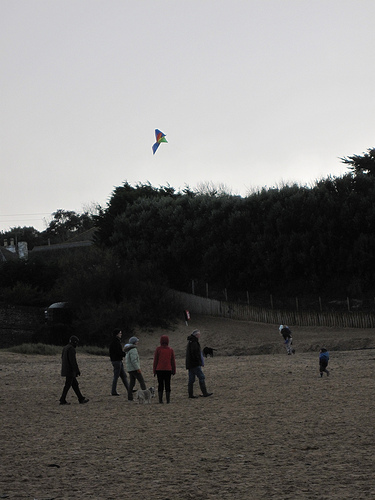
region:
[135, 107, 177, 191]
one kite in sky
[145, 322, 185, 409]
person in red shirt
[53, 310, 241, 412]
people in a field flying a kite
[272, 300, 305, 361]
one person away from others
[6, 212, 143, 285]
building in background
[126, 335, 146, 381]
person in a white shirt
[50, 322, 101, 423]
person wearing all black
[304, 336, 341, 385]
person in blue jacket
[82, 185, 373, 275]
trees in background of photo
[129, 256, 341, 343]
fence along side road in photo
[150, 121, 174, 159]
kite in the air is flying high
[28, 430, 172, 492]
sand looks dirty and rough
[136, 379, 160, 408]
dog on the sand looks happy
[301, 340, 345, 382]
little boy on the sand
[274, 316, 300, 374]
the girl is running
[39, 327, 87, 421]
man dressed in black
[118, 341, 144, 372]
the womans coat look warm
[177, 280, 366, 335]
a fence on the beach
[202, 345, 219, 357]
a black dog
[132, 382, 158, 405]
a dog on the leash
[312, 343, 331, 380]
a small child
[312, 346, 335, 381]
a light blue and black coat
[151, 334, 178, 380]
a red hooded winter coat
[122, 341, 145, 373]
a white coat with a furry collar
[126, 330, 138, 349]
a grey knit hat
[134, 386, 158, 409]
a white and grey dog on a leash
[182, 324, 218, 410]
an older man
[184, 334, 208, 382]
black hooded coat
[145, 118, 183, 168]
rainbow colored kite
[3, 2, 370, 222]
hazy grey sky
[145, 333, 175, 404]
young girl in red jacket.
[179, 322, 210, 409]
man standing on sandy beach.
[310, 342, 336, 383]
child on sandy beach.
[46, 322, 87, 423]
man walking across beach.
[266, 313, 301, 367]
man wearing a backpack.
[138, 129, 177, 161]
colorful kite in the sky.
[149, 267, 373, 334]
wooden fence along a hill.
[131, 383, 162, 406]
little white dog.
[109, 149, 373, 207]
brush covered hill side.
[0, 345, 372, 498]
foot print riddled sandy beach.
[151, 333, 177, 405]
person in red jacket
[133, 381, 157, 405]
dog going for a walk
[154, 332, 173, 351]
red jacket hood person wearing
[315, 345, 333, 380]
kid running in the field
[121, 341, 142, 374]
warm jacket person wearing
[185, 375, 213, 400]
boots guy is wearing for walk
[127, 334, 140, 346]
warm hat lady wearing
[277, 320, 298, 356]
person running through the field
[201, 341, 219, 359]
dog looking for bathroom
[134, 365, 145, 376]
red gloves worn by lady